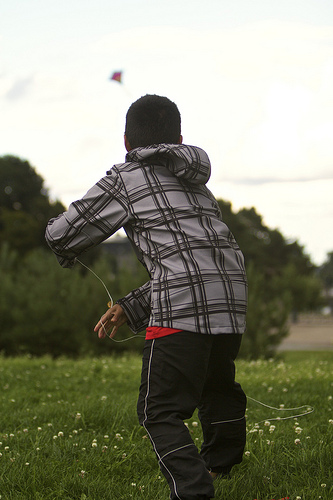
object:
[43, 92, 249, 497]
boy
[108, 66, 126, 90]
kite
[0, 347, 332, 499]
grass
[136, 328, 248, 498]
pants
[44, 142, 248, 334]
jacket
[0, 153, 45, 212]
trees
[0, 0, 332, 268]
sky